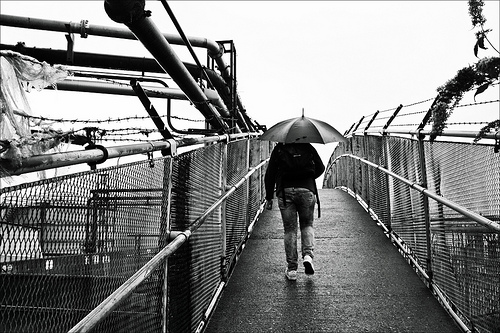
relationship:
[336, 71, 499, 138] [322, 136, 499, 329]
barbed wire on top of fence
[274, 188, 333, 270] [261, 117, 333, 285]
jeans on person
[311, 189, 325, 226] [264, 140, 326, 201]
strap hanging from sweater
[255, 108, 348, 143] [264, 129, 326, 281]
umbrella over person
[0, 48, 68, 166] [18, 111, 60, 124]
plastic on wire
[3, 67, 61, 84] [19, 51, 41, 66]
plastic on wire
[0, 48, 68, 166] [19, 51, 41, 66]
plastic on wire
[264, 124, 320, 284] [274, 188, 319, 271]
person wearing jeans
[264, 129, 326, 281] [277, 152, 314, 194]
person wearing jacket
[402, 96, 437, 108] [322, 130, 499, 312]
barbed wire on top fence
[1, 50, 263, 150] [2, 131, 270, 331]
barbed wire on top fence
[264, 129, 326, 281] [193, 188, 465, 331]
person walking up ramp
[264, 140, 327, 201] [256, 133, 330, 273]
sweater on person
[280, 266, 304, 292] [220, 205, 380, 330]
white shoe on ground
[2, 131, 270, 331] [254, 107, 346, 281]
fence beside person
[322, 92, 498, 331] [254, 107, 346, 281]
fence beside person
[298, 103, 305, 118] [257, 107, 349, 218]
point on umbrella